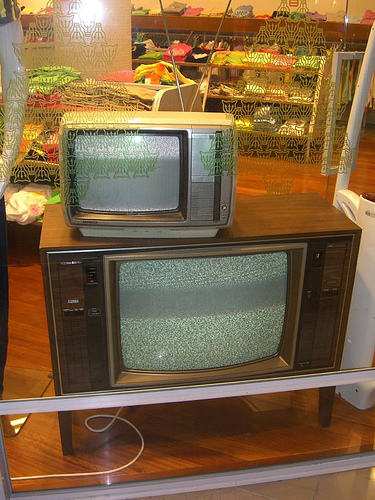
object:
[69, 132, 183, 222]
screen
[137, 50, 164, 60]
shirt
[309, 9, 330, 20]
shirt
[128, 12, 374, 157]
shelf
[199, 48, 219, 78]
antena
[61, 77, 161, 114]
clothes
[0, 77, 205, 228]
shelf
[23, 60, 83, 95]
clothes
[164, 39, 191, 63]
tee shirt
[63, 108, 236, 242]
tv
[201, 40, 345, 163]
shelf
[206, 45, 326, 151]
shirts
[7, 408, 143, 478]
cord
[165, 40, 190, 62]
shirt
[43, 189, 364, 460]
television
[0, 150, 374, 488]
floor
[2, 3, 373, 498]
store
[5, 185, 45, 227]
shirt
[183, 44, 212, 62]
folded shirt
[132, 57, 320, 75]
shelf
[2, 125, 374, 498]
ground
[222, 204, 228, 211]
button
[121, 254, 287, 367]
screen